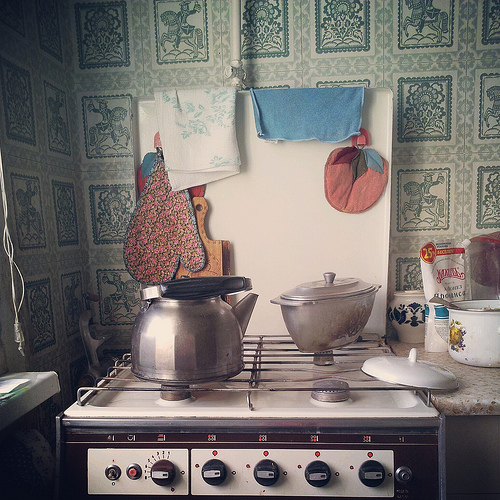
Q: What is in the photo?
A: Kitchenware.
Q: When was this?
A: Daytime.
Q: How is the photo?
A: Clear.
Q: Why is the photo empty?
A: There is no one.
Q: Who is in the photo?
A: Nobody.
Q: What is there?
A: A kettle.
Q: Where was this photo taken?
A: In a kitchen.